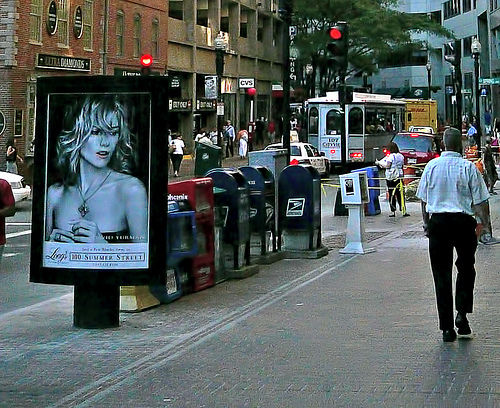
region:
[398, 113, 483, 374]
person walking at the sidewalk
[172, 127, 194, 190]
person walking at the sidewalk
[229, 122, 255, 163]
person walking at the sidewalk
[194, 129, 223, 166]
person walking at the sidewalk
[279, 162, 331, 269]
a blue mail post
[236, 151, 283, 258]
a blue mail post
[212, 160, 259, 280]
a blue mail post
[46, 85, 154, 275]
Poster of women in an advertisement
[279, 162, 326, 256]
United States Postal Mailbox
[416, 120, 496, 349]
Man walking down a busy street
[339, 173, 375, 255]
Newsstand on a sidewalk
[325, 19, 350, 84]
Stoplight showing red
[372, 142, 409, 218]
Women reading a paper on the street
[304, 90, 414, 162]
A streetcar driving on a busy street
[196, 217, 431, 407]
A brick Sidewalk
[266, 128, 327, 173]
A taxi cab on a busy street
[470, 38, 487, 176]
A street light on a busy street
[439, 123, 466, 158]
Person has short hair.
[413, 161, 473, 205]
Person wearing white shirt.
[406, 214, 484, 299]
Person wearing black pants.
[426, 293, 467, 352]
Person wearing dark shoes.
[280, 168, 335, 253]
Blue mailbox on sidewalk.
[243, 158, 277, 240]
Blue mailbox on sidewalk.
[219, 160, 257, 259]
Blue mailbox on sidewalk.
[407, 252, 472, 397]
Person walking on brick sidewalk.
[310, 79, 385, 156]
Trolley car driving on road.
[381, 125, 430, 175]
Red van driving on road.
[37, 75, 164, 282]
Poster with an advertisment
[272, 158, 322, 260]
A blue mailbox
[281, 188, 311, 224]
A post office sign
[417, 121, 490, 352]
A man walking on the street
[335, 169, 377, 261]
A white newspaper stand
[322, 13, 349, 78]
Traffic light with red signal light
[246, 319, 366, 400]
Gray cobblestone street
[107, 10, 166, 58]
Three windows on a building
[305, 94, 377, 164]
The front of a trolley car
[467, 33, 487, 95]
Antique lamp post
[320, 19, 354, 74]
Red stop light on a city street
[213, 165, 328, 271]
Three USPS mail boxes near curb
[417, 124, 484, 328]
Man in white shirt and black pants walking down sidewalk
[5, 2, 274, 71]
Buildings on a city street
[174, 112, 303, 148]
People walking down a sidewalk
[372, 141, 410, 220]
Woman reading newspaper near curb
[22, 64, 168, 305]
Woman's photo on advertisement board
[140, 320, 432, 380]
Sidewalk made from bricks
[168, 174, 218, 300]
Boxes that hold newspapers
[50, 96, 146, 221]
Photo of a blond woman wearing a necklace